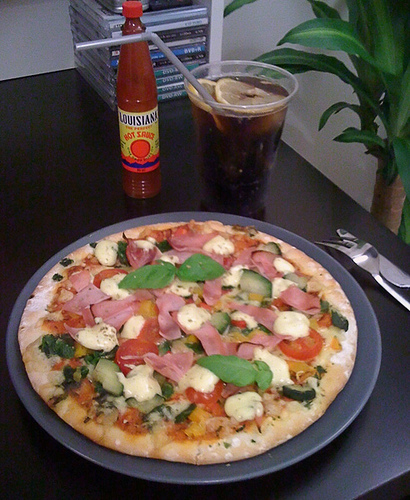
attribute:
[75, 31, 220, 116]
straw — gray, bending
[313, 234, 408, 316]
fork — silver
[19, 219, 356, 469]
pizza — small, uncut, cooked, baked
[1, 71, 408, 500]
table — black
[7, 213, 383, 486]
plate — blue, gray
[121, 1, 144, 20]
cap — red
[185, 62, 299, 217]
cup — plastic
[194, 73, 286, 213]
liquid — dark